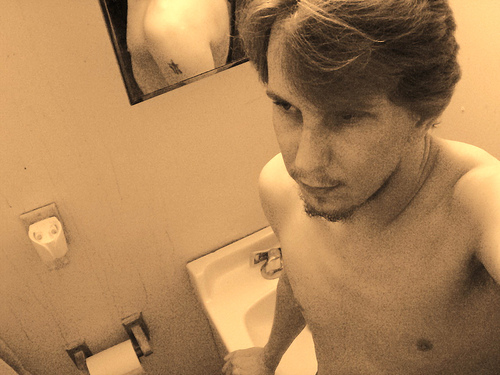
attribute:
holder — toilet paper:
[80, 310, 167, 372]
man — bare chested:
[213, 18, 468, 369]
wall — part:
[79, 113, 226, 240]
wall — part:
[4, 0, 258, 371]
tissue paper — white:
[24, 211, 78, 274]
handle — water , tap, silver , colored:
[253, 249, 285, 281]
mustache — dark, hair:
[288, 167, 342, 186]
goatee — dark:
[301, 201, 356, 221]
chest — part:
[274, 217, 494, 359]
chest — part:
[279, 241, 459, 373]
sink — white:
[185, 224, 314, 374]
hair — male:
[241, 0, 468, 118]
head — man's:
[227, 0, 462, 224]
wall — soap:
[4, 0, 499, 370]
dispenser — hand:
[20, 216, 70, 262]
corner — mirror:
[110, 77, 187, 117]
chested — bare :
[248, 202, 478, 359]